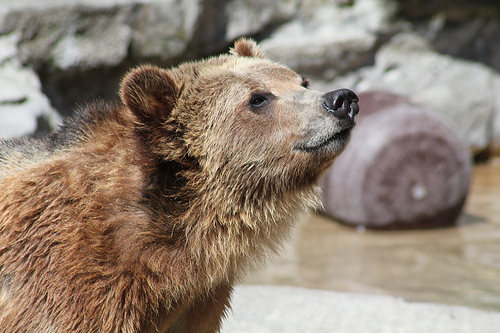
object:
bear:
[1, 36, 360, 332]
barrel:
[311, 87, 474, 230]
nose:
[321, 88, 360, 120]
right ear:
[120, 64, 181, 126]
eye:
[248, 89, 273, 109]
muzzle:
[290, 89, 360, 157]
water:
[289, 205, 499, 284]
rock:
[258, 0, 388, 75]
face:
[205, 68, 320, 165]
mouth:
[294, 122, 356, 151]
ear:
[230, 37, 266, 58]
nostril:
[335, 95, 344, 110]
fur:
[0, 113, 111, 195]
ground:
[218, 283, 500, 332]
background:
[0, 2, 498, 111]